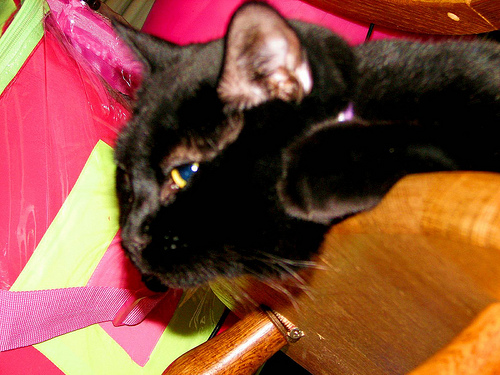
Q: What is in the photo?
A: A cat.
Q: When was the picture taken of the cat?
A: Daytime.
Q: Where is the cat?
A: On a stool.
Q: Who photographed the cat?
A: The pet owner.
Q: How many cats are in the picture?
A: One.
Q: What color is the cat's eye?
A: Blue.